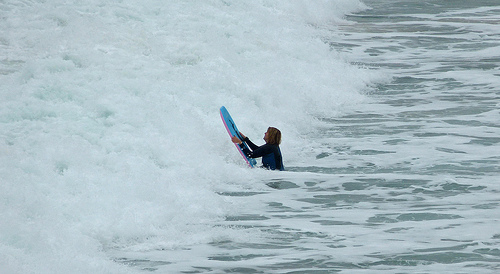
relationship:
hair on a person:
[266, 125, 283, 145] [234, 126, 285, 169]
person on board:
[234, 126, 285, 169] [210, 96, 262, 177]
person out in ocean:
[234, 126, 285, 169] [20, 57, 401, 232]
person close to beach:
[234, 124, 285, 169] [0, 0, 499, 271]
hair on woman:
[266, 125, 283, 145] [233, 124, 285, 167]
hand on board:
[230, 134, 239, 145] [217, 104, 256, 170]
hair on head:
[266, 125, 283, 145] [261, 124, 286, 150]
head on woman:
[261, 124, 286, 150] [225, 124, 287, 174]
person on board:
[234, 126, 285, 169] [217, 104, 256, 170]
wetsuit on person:
[240, 136, 285, 170] [234, 126, 285, 169]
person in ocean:
[234, 126, 285, 169] [4, 2, 498, 272]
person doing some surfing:
[234, 126, 285, 169] [168, 70, 336, 200]